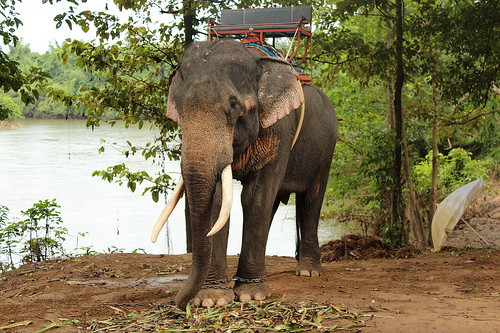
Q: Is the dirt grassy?
A: Yes, the dirt is grassy.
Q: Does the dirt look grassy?
A: Yes, the dirt is grassy.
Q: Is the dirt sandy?
A: No, the dirt is grassy.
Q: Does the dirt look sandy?
A: No, the dirt is grassy.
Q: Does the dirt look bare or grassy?
A: The dirt is grassy.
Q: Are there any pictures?
A: No, there are no pictures.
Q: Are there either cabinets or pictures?
A: No, there are no pictures or cabinets.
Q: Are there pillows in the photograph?
A: No, there are no pillows.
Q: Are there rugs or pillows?
A: No, there are no pillows or rugs.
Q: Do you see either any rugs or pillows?
A: No, there are no pillows or rugs.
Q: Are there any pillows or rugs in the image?
A: No, there are no pillows or rugs.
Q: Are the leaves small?
A: Yes, the leaves are small.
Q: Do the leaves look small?
A: Yes, the leaves are small.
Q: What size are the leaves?
A: The leaves are small.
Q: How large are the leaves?
A: The leaves are small.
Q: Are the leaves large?
A: No, the leaves are small.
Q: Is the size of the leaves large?
A: No, the leaves are small.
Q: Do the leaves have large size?
A: No, the leaves are small.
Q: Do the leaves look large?
A: No, the leaves are small.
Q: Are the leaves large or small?
A: The leaves are small.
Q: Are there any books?
A: No, there are no books.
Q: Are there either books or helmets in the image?
A: No, there are no books or helmets.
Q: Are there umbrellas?
A: Yes, there is an umbrella.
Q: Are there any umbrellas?
A: Yes, there is an umbrella.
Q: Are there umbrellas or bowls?
A: Yes, there is an umbrella.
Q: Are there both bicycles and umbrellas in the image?
A: No, there is an umbrella but no bicycles.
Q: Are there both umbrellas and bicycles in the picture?
A: No, there is an umbrella but no bicycles.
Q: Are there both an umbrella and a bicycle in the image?
A: No, there is an umbrella but no bicycles.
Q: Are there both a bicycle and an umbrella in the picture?
A: No, there is an umbrella but no bicycles.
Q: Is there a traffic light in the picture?
A: No, there are no traffic lights.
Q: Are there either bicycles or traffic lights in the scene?
A: No, there are no traffic lights or bicycles.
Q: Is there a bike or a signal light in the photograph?
A: No, there are no traffic lights or bikes.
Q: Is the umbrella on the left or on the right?
A: The umbrella is on the right of the image.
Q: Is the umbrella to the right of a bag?
A: No, the umbrella is to the right of an elephant.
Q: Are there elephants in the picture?
A: Yes, there is an elephant.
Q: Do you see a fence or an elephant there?
A: Yes, there is an elephant.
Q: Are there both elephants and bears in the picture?
A: No, there is an elephant but no bears.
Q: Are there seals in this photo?
A: No, there are no seals.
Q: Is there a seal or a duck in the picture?
A: No, there are no seals or ducks.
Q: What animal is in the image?
A: The animal is an elephant.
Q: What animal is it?
A: The animal is an elephant.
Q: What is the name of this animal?
A: This is an elephant.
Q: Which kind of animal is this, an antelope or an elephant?
A: This is an elephant.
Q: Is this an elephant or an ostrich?
A: This is an elephant.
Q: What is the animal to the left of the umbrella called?
A: The animal is an elephant.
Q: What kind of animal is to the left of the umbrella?
A: The animal is an elephant.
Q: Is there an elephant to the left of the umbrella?
A: Yes, there is an elephant to the left of the umbrella.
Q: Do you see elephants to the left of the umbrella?
A: Yes, there is an elephant to the left of the umbrella.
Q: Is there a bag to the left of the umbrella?
A: No, there is an elephant to the left of the umbrella.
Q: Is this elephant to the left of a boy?
A: No, the elephant is to the left of the umbrella.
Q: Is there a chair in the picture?
A: Yes, there is a chair.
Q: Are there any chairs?
A: Yes, there is a chair.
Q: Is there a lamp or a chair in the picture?
A: Yes, there is a chair.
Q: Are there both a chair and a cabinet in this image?
A: No, there is a chair but no cabinets.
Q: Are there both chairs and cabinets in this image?
A: No, there is a chair but no cabinets.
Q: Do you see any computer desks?
A: No, there are no computer desks.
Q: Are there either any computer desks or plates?
A: No, there are no computer desks or plates.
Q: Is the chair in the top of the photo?
A: Yes, the chair is in the top of the image.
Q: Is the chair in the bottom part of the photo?
A: No, the chair is in the top of the image.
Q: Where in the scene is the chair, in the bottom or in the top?
A: The chair is in the top of the image.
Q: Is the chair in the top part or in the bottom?
A: The chair is in the top of the image.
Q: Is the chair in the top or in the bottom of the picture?
A: The chair is in the top of the image.